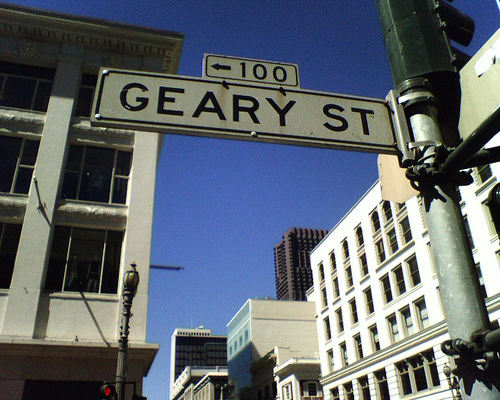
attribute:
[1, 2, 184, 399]
white building — tall, off white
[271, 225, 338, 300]
building — large, tall, brown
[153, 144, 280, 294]
sky — blue, cloudless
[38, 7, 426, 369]
sky — blue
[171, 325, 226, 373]
building — black and white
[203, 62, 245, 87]
arrow — black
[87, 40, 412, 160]
sign — white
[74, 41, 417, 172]
sign — black and white, white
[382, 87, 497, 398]
post — grey, metal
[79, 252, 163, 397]
light — red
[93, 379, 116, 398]
light — red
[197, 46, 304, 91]
sign — street, small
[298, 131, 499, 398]
building — large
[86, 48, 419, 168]
sign — black and white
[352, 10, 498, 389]
pole — tall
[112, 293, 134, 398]
pole — grey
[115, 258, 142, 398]
street light — Tall , metal 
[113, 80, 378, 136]
lettering — black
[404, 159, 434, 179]
bolts — large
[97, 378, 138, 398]
signal — electric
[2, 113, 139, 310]
windows — old